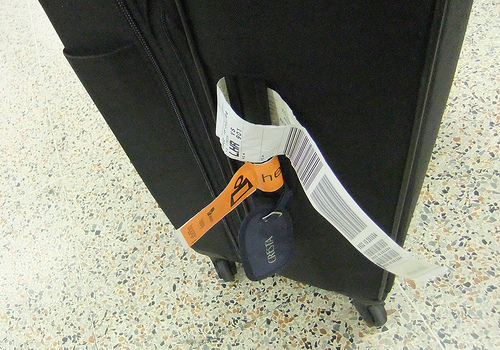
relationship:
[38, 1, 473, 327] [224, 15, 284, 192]
bag has handle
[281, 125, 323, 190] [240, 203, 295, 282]
barcode for scanning on tag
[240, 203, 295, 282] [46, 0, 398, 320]
tag attached to luggage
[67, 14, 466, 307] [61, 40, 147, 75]
bag has pocket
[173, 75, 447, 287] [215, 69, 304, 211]
travel tags on handle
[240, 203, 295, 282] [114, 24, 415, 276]
tag on suitcase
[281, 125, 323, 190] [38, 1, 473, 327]
barcode to bag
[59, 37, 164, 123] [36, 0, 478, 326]
pocket on side suitcase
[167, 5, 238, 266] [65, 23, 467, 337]
zipper of luggage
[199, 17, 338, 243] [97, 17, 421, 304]
handle of suitcase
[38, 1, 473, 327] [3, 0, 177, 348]
bag on floor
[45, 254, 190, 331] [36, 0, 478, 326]
floor under suitcase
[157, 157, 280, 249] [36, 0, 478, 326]
yellow tag on suitcase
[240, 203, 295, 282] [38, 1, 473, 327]
tag on bag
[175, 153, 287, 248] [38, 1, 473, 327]
tag on bag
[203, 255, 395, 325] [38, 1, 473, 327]
wheels on bag